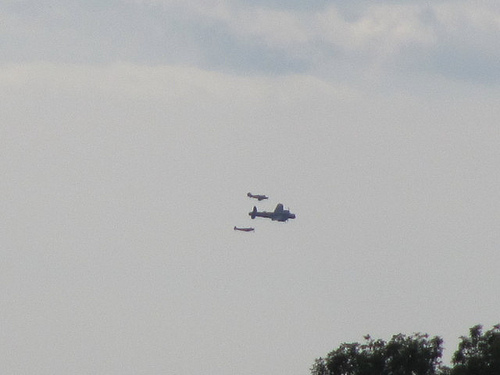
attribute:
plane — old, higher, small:
[245, 189, 268, 203]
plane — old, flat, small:
[232, 223, 256, 236]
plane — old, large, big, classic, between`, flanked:
[248, 203, 299, 225]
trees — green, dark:
[308, 323, 497, 375]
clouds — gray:
[220, 4, 499, 73]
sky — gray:
[2, 3, 500, 374]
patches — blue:
[3, 2, 500, 98]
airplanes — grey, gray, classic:
[233, 190, 299, 237]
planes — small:
[232, 191, 271, 235]